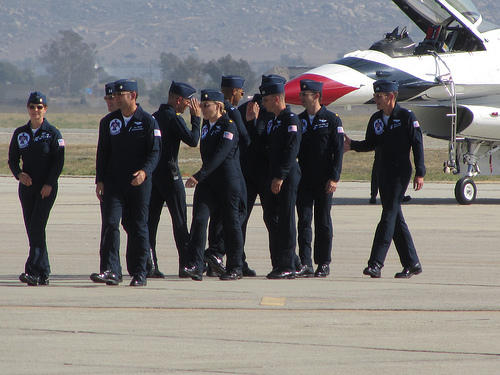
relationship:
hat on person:
[20, 87, 52, 100] [0, 95, 74, 294]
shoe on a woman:
[19, 270, 38, 287] [12, 92, 61, 280]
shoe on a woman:
[41, 271, 48, 281] [12, 92, 61, 280]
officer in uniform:
[10, 85, 60, 292] [7, 116, 64, 276]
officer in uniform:
[87, 79, 163, 286] [92, 104, 162, 274]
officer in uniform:
[327, 76, 425, 278] [347, 100, 427, 267]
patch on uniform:
[218, 127, 238, 141] [190, 109, 244, 274]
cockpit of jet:
[360, 9, 487, 61] [283, 0, 496, 201]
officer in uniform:
[6, 91, 64, 286] [7, 116, 64, 276]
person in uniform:
[185, 88, 245, 281] [186, 114, 248, 269]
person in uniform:
[289, 76, 344, 280] [293, 107, 343, 266]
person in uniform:
[246, 81, 303, 281] [260, 103, 301, 269]